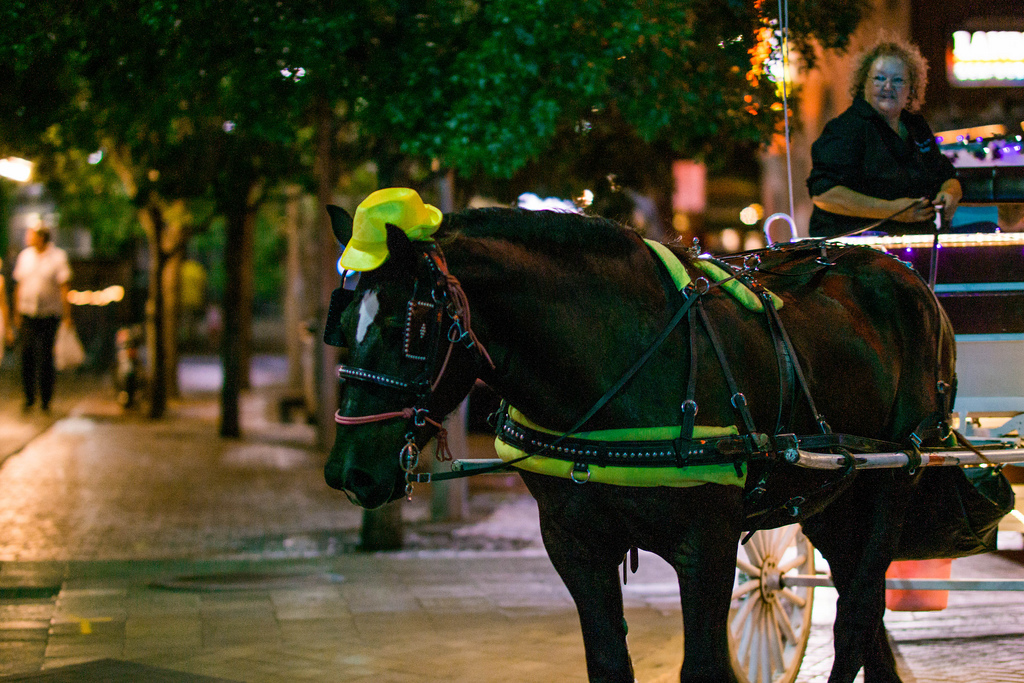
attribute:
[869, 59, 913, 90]
glasses — reading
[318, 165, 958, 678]
horse — brown, green, healthy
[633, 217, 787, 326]
trim — green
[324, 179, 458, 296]
hat — green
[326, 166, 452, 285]
hat — green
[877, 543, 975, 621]
container — orange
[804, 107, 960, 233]
shirt — black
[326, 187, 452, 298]
hat — small, yellow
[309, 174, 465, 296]
hat — yellow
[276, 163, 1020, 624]
horse — brown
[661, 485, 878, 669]
carriage wheel — white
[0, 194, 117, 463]
person — walking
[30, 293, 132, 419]
bag — white, plastic